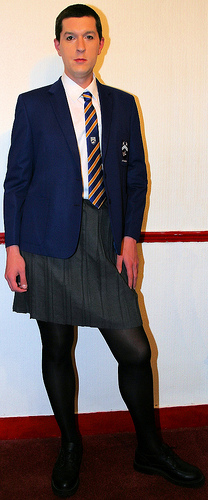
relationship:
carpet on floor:
[172, 416, 193, 446] [2, 437, 207, 499]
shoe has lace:
[55, 440, 88, 493] [161, 447, 181, 466]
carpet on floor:
[172, 416, 193, 446] [12, 445, 49, 495]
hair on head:
[51, 2, 103, 38] [52, 3, 105, 74]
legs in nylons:
[19, 252, 204, 497] [35, 327, 157, 443]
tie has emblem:
[82, 90, 107, 210] [88, 134, 99, 147]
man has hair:
[0, 0, 202, 484] [53, 3, 102, 45]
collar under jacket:
[59, 70, 99, 105] [3, 78, 148, 256]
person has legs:
[0, 0, 207, 496] [40, 252, 84, 497]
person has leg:
[0, 0, 207, 496] [89, 231, 172, 447]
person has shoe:
[0, 0, 207, 496] [45, 430, 86, 499]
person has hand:
[0, 0, 207, 496] [109, 226, 153, 286]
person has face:
[0, 0, 207, 496] [52, 10, 101, 79]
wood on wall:
[1, 230, 207, 243] [1, 1, 206, 497]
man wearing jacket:
[0, 0, 202, 484] [3, 78, 148, 256]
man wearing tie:
[0, 0, 202, 484] [81, 87, 108, 209]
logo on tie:
[87, 133, 98, 146] [78, 88, 110, 210]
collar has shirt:
[59, 70, 99, 105] [59, 72, 113, 201]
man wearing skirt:
[0, 0, 202, 484] [7, 197, 145, 330]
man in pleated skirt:
[0, 0, 202, 484] [9, 194, 155, 333]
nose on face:
[74, 37, 87, 53] [62, 17, 95, 76]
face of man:
[62, 17, 95, 76] [0, 0, 202, 484]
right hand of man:
[3, 243, 28, 293] [0, 0, 202, 484]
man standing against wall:
[0, 0, 167, 485] [1, 0, 207, 418]